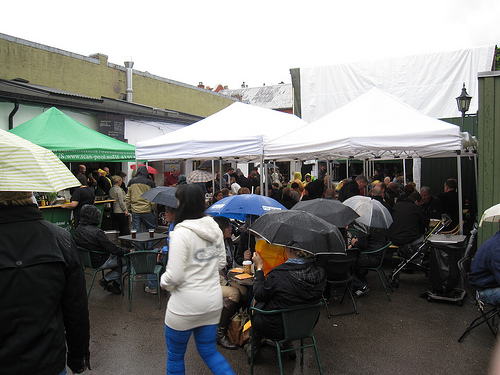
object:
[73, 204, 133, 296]
man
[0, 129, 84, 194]
umbrella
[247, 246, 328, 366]
person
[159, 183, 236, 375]
lady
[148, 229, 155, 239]
cup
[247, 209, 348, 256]
umbrella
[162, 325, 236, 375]
pant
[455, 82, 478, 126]
light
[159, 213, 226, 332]
shirt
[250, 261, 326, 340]
jacket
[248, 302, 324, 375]
chair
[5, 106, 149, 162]
canopy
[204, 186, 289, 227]
umbrella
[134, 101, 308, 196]
umbrella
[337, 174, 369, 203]
people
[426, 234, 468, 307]
garbage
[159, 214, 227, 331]
jacket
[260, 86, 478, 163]
canopy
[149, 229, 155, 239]
drink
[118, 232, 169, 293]
table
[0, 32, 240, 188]
building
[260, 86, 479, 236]
awning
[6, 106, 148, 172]
awning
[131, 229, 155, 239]
beer